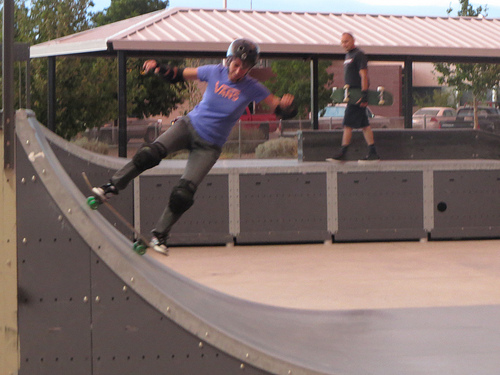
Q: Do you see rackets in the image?
A: No, there are no rackets.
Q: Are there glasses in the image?
A: No, there are no glasses.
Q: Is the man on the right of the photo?
A: Yes, the man is on the right of the image.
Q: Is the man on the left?
A: No, the man is on the right of the image.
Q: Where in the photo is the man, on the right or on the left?
A: The man is on the right of the image.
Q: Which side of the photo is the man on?
A: The man is on the right of the image.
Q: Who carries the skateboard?
A: The man carries the skateboard.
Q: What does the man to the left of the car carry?
A: The man carries a skateboard.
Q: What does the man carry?
A: The man carries a skateboard.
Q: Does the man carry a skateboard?
A: Yes, the man carries a skateboard.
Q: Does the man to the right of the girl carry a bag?
A: No, the man carries a skateboard.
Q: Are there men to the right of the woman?
A: Yes, there is a man to the right of the woman.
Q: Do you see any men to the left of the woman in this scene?
A: No, the man is to the right of the woman.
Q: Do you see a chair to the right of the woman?
A: No, there is a man to the right of the woman.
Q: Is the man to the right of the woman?
A: Yes, the man is to the right of the woman.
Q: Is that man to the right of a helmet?
A: No, the man is to the right of the woman.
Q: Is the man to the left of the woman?
A: No, the man is to the right of the woman.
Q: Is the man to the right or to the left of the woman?
A: The man is to the right of the woman.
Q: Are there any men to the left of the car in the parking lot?
A: Yes, there is a man to the left of the car.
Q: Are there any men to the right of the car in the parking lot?
A: No, the man is to the left of the car.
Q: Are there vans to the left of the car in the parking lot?
A: No, there is a man to the left of the car.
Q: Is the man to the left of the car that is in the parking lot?
A: Yes, the man is to the left of the car.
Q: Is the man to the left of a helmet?
A: No, the man is to the left of the car.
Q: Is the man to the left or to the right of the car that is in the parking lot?
A: The man is to the left of the car.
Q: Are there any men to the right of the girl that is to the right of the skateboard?
A: Yes, there is a man to the right of the girl.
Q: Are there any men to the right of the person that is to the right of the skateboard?
A: Yes, there is a man to the right of the girl.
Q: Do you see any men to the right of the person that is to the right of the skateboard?
A: Yes, there is a man to the right of the girl.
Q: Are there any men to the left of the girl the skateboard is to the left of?
A: No, the man is to the right of the girl.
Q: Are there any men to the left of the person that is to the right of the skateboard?
A: No, the man is to the right of the girl.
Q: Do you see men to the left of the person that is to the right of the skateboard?
A: No, the man is to the right of the girl.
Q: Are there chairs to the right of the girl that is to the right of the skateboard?
A: No, there is a man to the right of the girl.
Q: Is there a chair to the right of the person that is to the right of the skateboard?
A: No, there is a man to the right of the girl.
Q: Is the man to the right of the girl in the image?
A: Yes, the man is to the right of the girl.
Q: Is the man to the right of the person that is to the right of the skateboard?
A: Yes, the man is to the right of the girl.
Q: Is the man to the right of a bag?
A: No, the man is to the right of the girl.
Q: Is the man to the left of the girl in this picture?
A: No, the man is to the right of the girl.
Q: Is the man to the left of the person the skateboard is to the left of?
A: No, the man is to the right of the girl.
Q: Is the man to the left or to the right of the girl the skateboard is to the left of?
A: The man is to the right of the girl.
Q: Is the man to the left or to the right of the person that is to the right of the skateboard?
A: The man is to the right of the girl.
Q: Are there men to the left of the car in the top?
A: Yes, there is a man to the left of the car.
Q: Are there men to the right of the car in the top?
A: No, the man is to the left of the car.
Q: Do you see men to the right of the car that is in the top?
A: No, the man is to the left of the car.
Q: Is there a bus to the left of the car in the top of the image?
A: No, there is a man to the left of the car.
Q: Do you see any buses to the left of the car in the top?
A: No, there is a man to the left of the car.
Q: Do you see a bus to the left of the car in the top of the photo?
A: No, there is a man to the left of the car.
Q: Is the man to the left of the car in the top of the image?
A: Yes, the man is to the left of the car.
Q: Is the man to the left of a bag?
A: No, the man is to the left of the car.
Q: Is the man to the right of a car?
A: No, the man is to the left of a car.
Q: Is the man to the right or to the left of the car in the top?
A: The man is to the left of the car.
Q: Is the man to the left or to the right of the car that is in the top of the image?
A: The man is to the left of the car.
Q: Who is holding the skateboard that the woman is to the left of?
A: The man is holding the skateboard.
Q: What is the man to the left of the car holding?
A: The man is holding the skateboard.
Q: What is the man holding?
A: The man is holding the skateboard.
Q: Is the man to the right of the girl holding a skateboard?
A: Yes, the man is holding a skateboard.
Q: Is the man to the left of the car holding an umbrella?
A: No, the man is holding a skateboard.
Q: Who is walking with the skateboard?
A: The man is walking with the skateboard.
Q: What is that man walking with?
A: The man is walking with a skateboard.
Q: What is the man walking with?
A: The man is walking with a skateboard.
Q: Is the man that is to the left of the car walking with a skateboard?
A: Yes, the man is walking with a skateboard.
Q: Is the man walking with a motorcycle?
A: No, the man is walking with a skateboard.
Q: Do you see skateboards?
A: Yes, there is a skateboard.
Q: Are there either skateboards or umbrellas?
A: Yes, there is a skateboard.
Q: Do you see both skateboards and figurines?
A: No, there is a skateboard but no figurines.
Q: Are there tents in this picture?
A: No, there are no tents.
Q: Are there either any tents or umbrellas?
A: No, there are no tents or umbrellas.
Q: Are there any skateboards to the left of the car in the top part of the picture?
A: Yes, there is a skateboard to the left of the car.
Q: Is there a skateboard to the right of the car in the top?
A: No, the skateboard is to the left of the car.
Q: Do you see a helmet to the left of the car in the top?
A: No, there is a skateboard to the left of the car.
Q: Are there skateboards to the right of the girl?
A: Yes, there is a skateboard to the right of the girl.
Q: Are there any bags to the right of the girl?
A: No, there is a skateboard to the right of the girl.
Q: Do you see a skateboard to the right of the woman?
A: Yes, there is a skateboard to the right of the woman.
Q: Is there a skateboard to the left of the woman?
A: No, the skateboard is to the right of the woman.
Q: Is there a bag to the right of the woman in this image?
A: No, there is a skateboard to the right of the woman.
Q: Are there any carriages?
A: No, there are no carriages.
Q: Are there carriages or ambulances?
A: No, there are no carriages or ambulances.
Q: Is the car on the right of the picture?
A: Yes, the car is on the right of the image.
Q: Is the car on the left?
A: No, the car is on the right of the image.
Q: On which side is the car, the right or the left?
A: The car is on the right of the image.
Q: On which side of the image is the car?
A: The car is on the right of the image.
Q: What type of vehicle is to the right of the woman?
A: The vehicle is a car.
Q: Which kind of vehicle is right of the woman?
A: The vehicle is a car.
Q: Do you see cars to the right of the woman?
A: Yes, there is a car to the right of the woman.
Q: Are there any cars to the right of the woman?
A: Yes, there is a car to the right of the woman.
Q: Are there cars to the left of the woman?
A: No, the car is to the right of the woman.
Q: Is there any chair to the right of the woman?
A: No, there is a car to the right of the woman.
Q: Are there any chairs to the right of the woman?
A: No, there is a car to the right of the woman.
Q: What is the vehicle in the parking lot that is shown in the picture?
A: The vehicle is a car.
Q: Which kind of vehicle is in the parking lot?
A: The vehicle is a car.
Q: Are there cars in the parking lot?
A: Yes, there is a car in the parking lot.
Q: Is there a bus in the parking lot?
A: No, there is a car in the parking lot.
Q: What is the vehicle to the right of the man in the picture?
A: The vehicle is a car.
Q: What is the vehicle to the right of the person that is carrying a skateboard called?
A: The vehicle is a car.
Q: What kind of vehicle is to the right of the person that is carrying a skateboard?
A: The vehicle is a car.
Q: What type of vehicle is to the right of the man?
A: The vehicle is a car.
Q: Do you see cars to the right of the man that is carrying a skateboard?
A: Yes, there is a car to the right of the man.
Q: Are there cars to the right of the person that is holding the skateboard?
A: Yes, there is a car to the right of the man.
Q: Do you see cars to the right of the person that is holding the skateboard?
A: Yes, there is a car to the right of the man.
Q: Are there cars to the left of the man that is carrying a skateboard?
A: No, the car is to the right of the man.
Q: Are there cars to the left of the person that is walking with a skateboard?
A: No, the car is to the right of the man.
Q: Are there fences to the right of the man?
A: No, there is a car to the right of the man.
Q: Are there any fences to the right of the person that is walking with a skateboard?
A: No, there is a car to the right of the man.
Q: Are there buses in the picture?
A: No, there are no buses.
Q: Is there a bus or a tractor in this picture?
A: No, there are no buses or tractors.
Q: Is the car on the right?
A: Yes, the car is on the right of the image.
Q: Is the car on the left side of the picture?
A: No, the car is on the right of the image.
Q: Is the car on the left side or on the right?
A: The car is on the right of the image.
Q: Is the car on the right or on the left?
A: The car is on the right of the image.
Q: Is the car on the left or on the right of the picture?
A: The car is on the right of the image.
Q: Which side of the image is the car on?
A: The car is on the right of the image.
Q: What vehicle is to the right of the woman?
A: The vehicle is a car.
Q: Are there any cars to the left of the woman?
A: No, the car is to the right of the woman.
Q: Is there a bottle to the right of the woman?
A: No, there is a car to the right of the woman.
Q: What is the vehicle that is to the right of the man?
A: The vehicle is a car.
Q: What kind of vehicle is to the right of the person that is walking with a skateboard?
A: The vehicle is a car.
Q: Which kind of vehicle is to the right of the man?
A: The vehicle is a car.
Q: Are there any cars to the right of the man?
A: Yes, there is a car to the right of the man.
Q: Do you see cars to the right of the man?
A: Yes, there is a car to the right of the man.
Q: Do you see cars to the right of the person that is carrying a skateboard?
A: Yes, there is a car to the right of the man.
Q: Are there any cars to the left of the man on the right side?
A: No, the car is to the right of the man.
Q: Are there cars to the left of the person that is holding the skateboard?
A: No, the car is to the right of the man.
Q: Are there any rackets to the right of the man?
A: No, there is a car to the right of the man.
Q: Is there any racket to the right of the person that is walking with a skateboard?
A: No, there is a car to the right of the man.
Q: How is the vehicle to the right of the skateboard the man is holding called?
A: The vehicle is a car.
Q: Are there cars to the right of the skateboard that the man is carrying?
A: Yes, there is a car to the right of the skateboard.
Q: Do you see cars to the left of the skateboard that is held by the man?
A: No, the car is to the right of the skateboard.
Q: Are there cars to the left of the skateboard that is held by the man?
A: No, the car is to the right of the skateboard.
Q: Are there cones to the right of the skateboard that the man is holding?
A: No, there is a car to the right of the skateboard.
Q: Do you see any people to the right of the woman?
A: Yes, there is a person to the right of the woman.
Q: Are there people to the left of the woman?
A: No, the person is to the right of the woman.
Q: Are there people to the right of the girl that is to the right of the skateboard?
A: Yes, there is a person to the right of the girl.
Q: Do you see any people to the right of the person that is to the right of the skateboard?
A: Yes, there is a person to the right of the girl.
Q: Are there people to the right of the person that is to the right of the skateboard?
A: Yes, there is a person to the right of the girl.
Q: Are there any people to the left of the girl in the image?
A: No, the person is to the right of the girl.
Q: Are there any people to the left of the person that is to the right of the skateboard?
A: No, the person is to the right of the girl.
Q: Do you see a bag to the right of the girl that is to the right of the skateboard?
A: No, there is a person to the right of the girl.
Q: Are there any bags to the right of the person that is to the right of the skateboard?
A: No, there is a person to the right of the girl.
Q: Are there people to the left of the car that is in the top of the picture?
A: Yes, there is a person to the left of the car.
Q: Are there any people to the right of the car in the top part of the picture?
A: No, the person is to the left of the car.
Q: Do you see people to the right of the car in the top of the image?
A: No, the person is to the left of the car.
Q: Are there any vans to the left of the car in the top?
A: No, there is a person to the left of the car.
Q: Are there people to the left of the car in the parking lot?
A: Yes, there is a person to the left of the car.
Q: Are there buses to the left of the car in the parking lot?
A: No, there is a person to the left of the car.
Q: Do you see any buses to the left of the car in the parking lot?
A: No, there is a person to the left of the car.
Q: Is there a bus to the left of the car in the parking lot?
A: No, there is a person to the left of the car.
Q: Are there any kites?
A: No, there are no kites.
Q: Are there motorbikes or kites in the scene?
A: No, there are no kites or motorbikes.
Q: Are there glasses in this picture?
A: No, there are no glasses.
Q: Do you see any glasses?
A: No, there are no glasses.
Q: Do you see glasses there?
A: No, there are no glasses.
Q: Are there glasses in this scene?
A: No, there are no glasses.